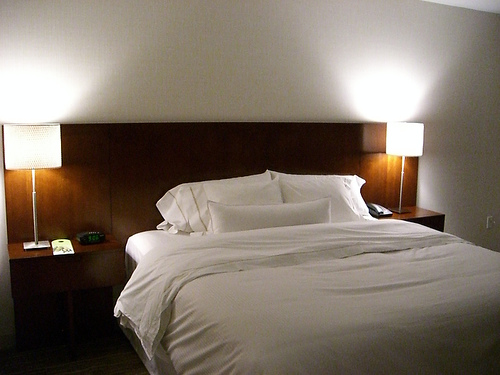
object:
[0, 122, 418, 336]
wall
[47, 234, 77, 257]
hanger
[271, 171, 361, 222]
pillow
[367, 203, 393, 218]
gray phone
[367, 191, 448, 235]
night stand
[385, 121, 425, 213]
lamp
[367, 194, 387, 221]
phone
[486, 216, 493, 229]
socket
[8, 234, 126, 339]
desk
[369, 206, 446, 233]
desk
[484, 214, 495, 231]
outlet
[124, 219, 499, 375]
bed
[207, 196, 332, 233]
pillow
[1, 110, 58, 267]
lamp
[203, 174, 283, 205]
white pillows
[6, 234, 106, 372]
night stand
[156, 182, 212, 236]
pillowcase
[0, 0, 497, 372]
room